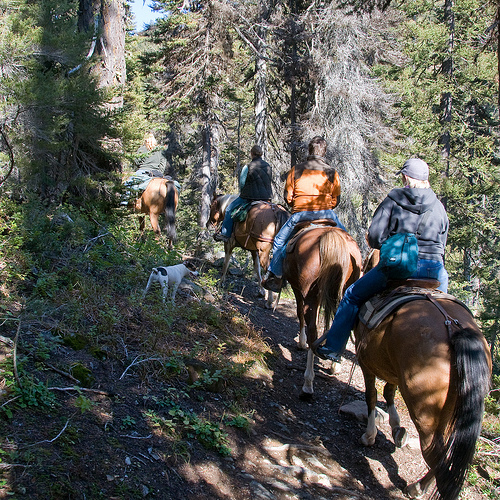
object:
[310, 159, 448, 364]
person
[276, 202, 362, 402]
horse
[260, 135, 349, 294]
person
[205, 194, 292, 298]
horse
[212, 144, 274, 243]
person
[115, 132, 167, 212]
person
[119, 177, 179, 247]
horses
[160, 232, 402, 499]
path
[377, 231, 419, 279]
bag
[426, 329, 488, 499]
tail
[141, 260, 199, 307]
dog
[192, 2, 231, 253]
trees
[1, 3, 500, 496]
woods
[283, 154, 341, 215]
jacket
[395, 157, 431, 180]
cap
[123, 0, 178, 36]
sky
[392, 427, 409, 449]
back hoof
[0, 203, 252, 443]
grass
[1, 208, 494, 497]
ground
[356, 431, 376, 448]
hooves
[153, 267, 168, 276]
spot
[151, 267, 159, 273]
tail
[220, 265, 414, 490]
shadow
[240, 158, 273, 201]
vest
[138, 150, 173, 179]
jacket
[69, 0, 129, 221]
tree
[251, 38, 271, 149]
trunk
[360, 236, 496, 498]
horse